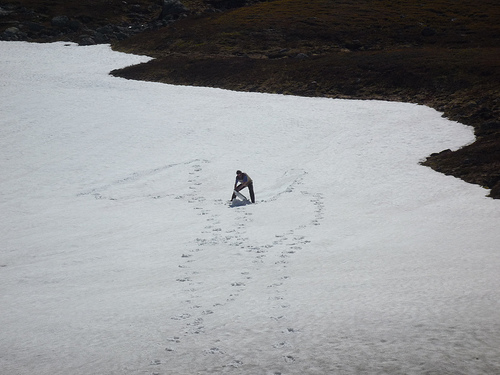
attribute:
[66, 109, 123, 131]
snow — smooth, white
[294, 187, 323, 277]
tracks — dirty, shaped, cool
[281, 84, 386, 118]
edge — odd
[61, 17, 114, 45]
boulders — distant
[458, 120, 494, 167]
mountain — dark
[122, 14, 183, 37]
lights — distant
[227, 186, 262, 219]
skis — white